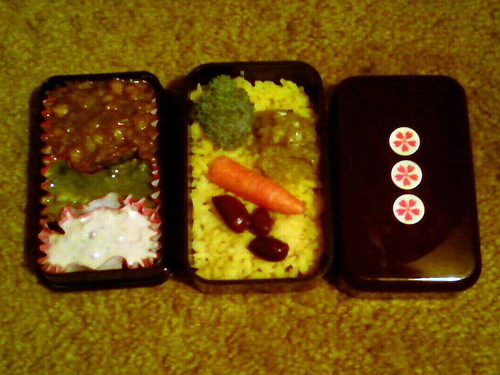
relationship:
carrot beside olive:
[207, 157, 306, 215] [213, 194, 248, 232]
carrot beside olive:
[207, 157, 306, 215] [250, 206, 272, 236]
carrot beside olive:
[207, 157, 306, 215] [246, 236, 288, 261]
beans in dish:
[41, 82, 163, 192] [31, 73, 176, 295]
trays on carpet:
[49, 73, 490, 283] [145, 286, 436, 338]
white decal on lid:
[388, 120, 426, 225] [334, 72, 480, 284]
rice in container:
[191, 79, 318, 270] [167, 51, 332, 290]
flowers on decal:
[395, 165, 420, 220] [391, 126, 419, 153]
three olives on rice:
[198, 187, 283, 259] [198, 180, 309, 277]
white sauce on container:
[43, 202, 155, 271] [22, 67, 177, 294]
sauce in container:
[47, 172, 154, 201] [22, 67, 177, 294]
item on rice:
[200, 79, 256, 148] [197, 82, 307, 277]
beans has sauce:
[41, 82, 163, 192] [63, 169, 150, 194]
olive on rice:
[246, 236, 288, 261] [191, 79, 318, 270]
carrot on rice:
[207, 157, 306, 215] [193, 223, 255, 280]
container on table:
[26, 73, 172, 285] [5, 2, 497, 370]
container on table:
[167, 51, 332, 290] [5, 2, 497, 370]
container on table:
[326, 73, 492, 296] [5, 2, 497, 370]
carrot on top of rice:
[207, 157, 311, 216] [191, 79, 318, 270]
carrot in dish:
[207, 157, 311, 216] [168, 66, 328, 293]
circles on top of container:
[387, 123, 426, 231] [27, 53, 479, 280]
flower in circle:
[391, 127, 418, 151] [388, 125, 420, 155]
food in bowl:
[40, 195, 160, 272] [25, 65, 175, 292]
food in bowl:
[38, 154, 155, 210] [25, 65, 175, 292]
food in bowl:
[38, 74, 158, 170] [25, 65, 175, 292]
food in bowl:
[192, 74, 257, 153] [176, 59, 338, 297]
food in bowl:
[204, 150, 311, 215] [176, 59, 338, 297]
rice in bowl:
[191, 79, 317, 280] [176, 59, 338, 297]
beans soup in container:
[50, 80, 155, 168] [22, 67, 177, 294]